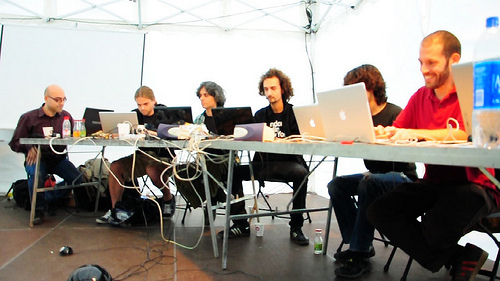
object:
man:
[364, 30, 499, 281]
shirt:
[387, 83, 498, 194]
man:
[324, 63, 421, 280]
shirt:
[362, 102, 419, 182]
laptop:
[290, 101, 337, 140]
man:
[215, 70, 307, 248]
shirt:
[252, 101, 315, 164]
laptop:
[210, 107, 257, 140]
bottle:
[470, 13, 499, 152]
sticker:
[472, 59, 500, 110]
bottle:
[80, 119, 86, 139]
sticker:
[82, 128, 88, 140]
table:
[18, 131, 499, 270]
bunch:
[48, 131, 233, 279]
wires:
[46, 130, 208, 178]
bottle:
[63, 116, 70, 140]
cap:
[64, 115, 71, 120]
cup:
[41, 127, 55, 138]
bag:
[3, 178, 44, 212]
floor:
[1, 189, 500, 280]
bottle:
[313, 228, 326, 256]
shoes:
[215, 218, 259, 239]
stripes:
[230, 227, 247, 237]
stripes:
[290, 231, 300, 240]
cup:
[254, 221, 266, 238]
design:
[254, 227, 259, 232]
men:
[10, 88, 96, 223]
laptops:
[96, 110, 139, 136]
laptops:
[149, 105, 195, 140]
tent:
[5, 0, 493, 206]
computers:
[314, 80, 411, 143]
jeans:
[327, 168, 413, 252]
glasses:
[46, 94, 69, 103]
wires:
[53, 209, 250, 280]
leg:
[221, 151, 237, 270]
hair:
[257, 70, 296, 102]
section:
[1, 15, 152, 145]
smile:
[421, 71, 441, 85]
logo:
[338, 110, 347, 121]